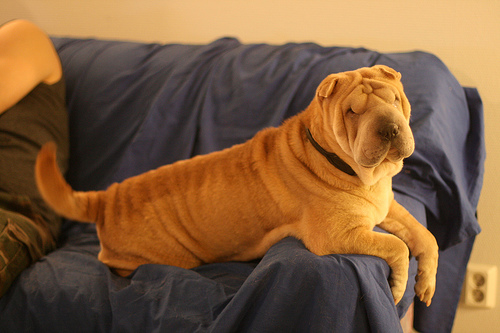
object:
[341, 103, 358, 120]
eye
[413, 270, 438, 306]
foot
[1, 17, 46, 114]
arm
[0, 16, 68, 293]
man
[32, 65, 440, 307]
dog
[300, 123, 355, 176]
collar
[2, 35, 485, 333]
couch cover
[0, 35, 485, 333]
couch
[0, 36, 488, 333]
sheet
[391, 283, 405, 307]
foot